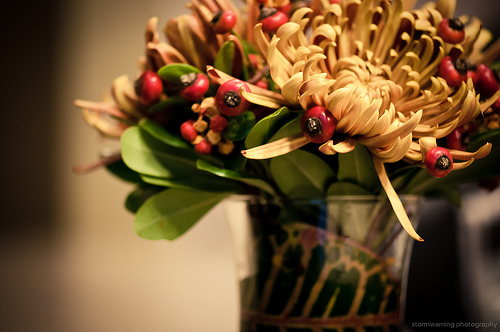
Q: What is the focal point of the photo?
A: Flowers in a vase.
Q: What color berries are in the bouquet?
A: Red.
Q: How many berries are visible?
A: Sixteen.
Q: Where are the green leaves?
A: Between the top of the vase and the flowers.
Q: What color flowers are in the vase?
A: Beige / light yellow.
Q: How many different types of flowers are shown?
A: One.